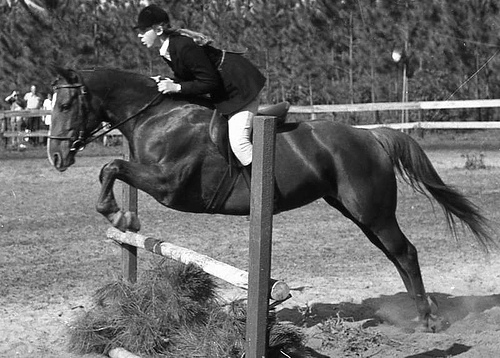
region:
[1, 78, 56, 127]
spectators watching horse jump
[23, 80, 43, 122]
man wearing white shirt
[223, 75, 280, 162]
rider wearing tight white pants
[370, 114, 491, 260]
black horse's tail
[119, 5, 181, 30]
rider wearing black cap with brim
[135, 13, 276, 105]
rider wearing black jacket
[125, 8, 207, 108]
rider holding horse's rein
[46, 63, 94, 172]
reins around horse's head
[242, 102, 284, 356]
long black post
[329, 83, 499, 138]
large white fence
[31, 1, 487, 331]
Equestrian Jumping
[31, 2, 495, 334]
Girl riding a horse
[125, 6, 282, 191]
Woman rider jumping with horse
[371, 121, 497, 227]
Long hairy tail of horse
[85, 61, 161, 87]
Mane of horse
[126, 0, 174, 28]
Helmet of rider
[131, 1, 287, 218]
Rider with white pants and black boots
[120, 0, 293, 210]
Rider with black jacket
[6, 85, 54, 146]
People observing the rider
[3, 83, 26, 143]
Man taking a picture of rider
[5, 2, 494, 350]
Horse racing in afield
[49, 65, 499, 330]
Brown horse jumping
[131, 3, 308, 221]
Rider on a horse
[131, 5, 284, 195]
Horse rider wearing black helmet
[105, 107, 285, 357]
equestrian obstacle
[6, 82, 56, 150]
Tree person watching a horse rider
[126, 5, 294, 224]
Rider wearing black boots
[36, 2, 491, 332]
Girl on a horse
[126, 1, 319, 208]
Horse rider wearing a black helmet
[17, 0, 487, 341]
Horse racing over a hurdle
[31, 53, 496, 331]
Horse jumping over a hurdle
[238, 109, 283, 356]
Pole of a hurdle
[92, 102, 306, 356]
Hurdle for horse race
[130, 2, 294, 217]
Rider wearing white pants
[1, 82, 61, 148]
People observing a horse race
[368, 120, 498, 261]
Long horse race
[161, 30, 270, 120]
Jacket of horse rider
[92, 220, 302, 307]
Horizontal stick of hurdle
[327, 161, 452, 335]
Legs of horse